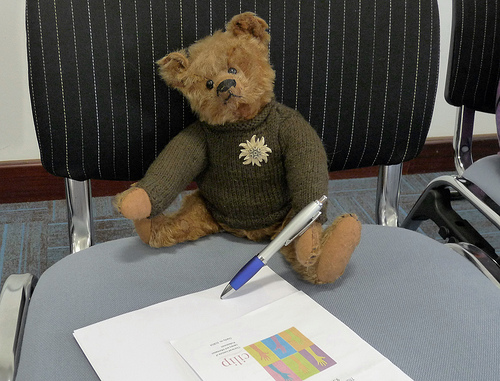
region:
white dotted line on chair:
[416, 1, 436, 159]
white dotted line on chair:
[399, 2, 424, 160]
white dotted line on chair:
[371, 1, 403, 166]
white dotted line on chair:
[343, 2, 368, 168]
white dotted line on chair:
[331, 4, 352, 168]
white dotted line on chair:
[278, 3, 290, 95]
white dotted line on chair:
[236, 1, 244, 11]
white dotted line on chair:
[221, 4, 229, 29]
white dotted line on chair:
[191, 1, 201, 47]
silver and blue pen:
[222, 191, 331, 296]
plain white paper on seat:
[67, 262, 297, 379]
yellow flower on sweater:
[239, 135, 273, 172]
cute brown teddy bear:
[122, 10, 359, 281]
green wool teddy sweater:
[134, 99, 331, 233]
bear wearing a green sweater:
[125, 7, 364, 282]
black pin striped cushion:
[26, 0, 444, 174]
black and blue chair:
[14, 0, 498, 378]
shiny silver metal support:
[62, 170, 94, 253]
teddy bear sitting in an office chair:
[26, 15, 489, 370]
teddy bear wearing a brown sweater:
[122, 18, 360, 285]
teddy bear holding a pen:
[125, 27, 328, 304]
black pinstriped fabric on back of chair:
[40, 0, 447, 178]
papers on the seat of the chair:
[77, 270, 339, 372]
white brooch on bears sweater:
[224, 129, 280, 175]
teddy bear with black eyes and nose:
[189, 58, 258, 116]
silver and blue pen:
[212, 187, 337, 313]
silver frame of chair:
[60, 164, 107, 257]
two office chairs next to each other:
[12, 4, 488, 369]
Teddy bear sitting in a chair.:
[34, 9, 449, 379]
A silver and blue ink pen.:
[215, 183, 328, 304]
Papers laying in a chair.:
[67, 272, 422, 378]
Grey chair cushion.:
[35, 222, 496, 377]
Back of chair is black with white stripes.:
[23, 1, 423, 161]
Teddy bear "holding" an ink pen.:
[116, 3, 356, 293]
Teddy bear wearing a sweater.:
[112, 10, 368, 281]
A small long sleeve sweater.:
[128, 113, 330, 226]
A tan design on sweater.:
[230, 132, 271, 169]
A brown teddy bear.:
[103, 18, 372, 292]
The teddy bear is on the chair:
[140, 65, 392, 377]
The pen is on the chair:
[205, 193, 334, 302]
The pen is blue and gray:
[213, 183, 313, 299]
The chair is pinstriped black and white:
[38, 21, 140, 137]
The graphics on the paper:
[181, 297, 341, 379]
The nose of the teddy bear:
[211, 74, 241, 101]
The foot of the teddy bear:
[313, 208, 363, 290]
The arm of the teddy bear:
[106, 128, 205, 223]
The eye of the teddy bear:
[198, 70, 218, 91]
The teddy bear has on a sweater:
[126, 95, 337, 237]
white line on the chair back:
[82, 0, 107, 174]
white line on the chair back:
[145, 0, 157, 158]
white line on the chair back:
[288, 0, 300, 112]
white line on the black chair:
[51, 0, 69, 183]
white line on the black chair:
[81, 0, 106, 179]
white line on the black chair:
[116, 2, 131, 178]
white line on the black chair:
[148, 0, 160, 159]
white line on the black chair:
[290, 0, 300, 110]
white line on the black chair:
[305, 0, 316, 123]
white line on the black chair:
[320, 0, 333, 139]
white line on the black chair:
[330, 0, 343, 163]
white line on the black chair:
[345, 1, 362, 171]